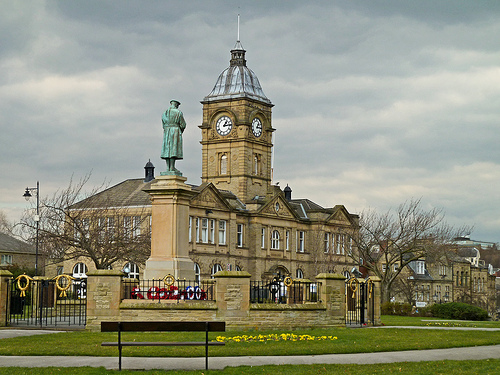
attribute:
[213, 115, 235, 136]
clock face — white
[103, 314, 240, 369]
bench — wood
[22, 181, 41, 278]
street lamp — tall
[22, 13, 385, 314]
building — brick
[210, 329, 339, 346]
flowers — yellow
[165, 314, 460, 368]
grass — green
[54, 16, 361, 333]
building — big, fancy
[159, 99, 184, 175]
statue — green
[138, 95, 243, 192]
statute — weathered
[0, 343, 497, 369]
path — walking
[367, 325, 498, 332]
path — walking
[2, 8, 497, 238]
clouds — dark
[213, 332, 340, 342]
plants — yellow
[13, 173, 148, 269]
tree — leafless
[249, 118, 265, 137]
clock — large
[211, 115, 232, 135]
clock — large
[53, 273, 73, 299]
decoration — golden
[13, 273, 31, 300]
decoration — golden